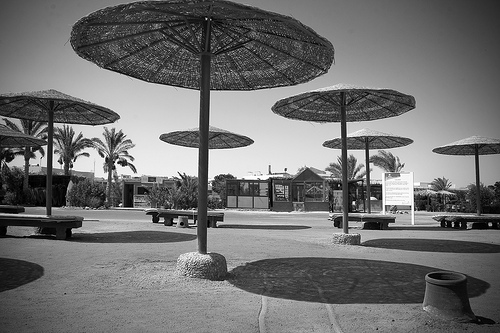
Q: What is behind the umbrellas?
A: Palm trees.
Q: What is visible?
A: Umbrella.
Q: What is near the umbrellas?
A: Tables.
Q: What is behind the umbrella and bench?
A: A sign.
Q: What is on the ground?
A: Ths shadow.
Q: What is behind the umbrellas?
A: A building.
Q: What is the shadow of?
A: A umbrella.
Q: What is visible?
A: A umbrella.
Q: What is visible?
A: A umbrella.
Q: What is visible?
A: Palm trees.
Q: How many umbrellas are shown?
A: 7.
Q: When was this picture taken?
A: Daytime.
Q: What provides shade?
A: Umbrellas.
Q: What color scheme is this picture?
A: Black and white.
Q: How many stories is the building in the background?
A: 1.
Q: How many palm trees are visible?
A: 6.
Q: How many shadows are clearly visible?
A: 5.